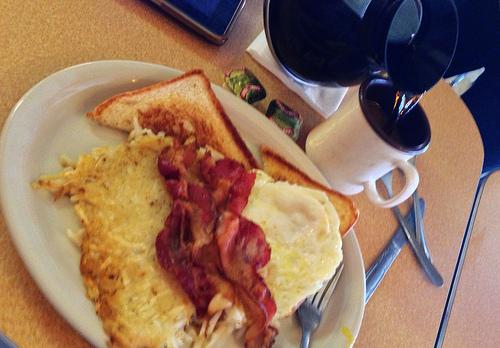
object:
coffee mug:
[303, 77, 433, 209]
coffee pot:
[261, 0, 461, 94]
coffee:
[368, 87, 425, 142]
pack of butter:
[265, 98, 305, 141]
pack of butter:
[223, 67, 267, 105]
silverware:
[367, 161, 444, 309]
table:
[0, 0, 499, 348]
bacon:
[157, 137, 221, 321]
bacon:
[200, 150, 281, 347]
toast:
[85, 68, 263, 173]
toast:
[259, 144, 360, 240]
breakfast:
[35, 68, 361, 348]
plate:
[0, 60, 366, 348]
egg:
[244, 168, 343, 316]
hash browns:
[30, 114, 206, 347]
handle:
[362, 161, 421, 209]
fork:
[297, 262, 344, 348]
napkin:
[243, 29, 350, 121]